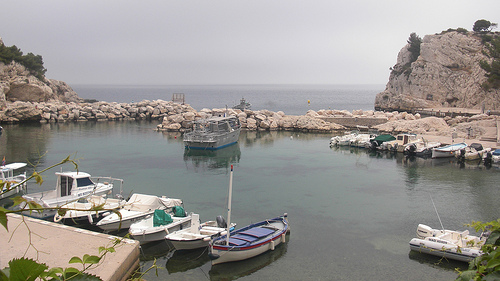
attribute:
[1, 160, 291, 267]
boats — lined, reflected, seven, several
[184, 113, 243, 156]
boat — large, alone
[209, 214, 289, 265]
boat — blue, small, white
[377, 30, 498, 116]
cliff — large, rocky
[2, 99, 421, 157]
rocks — reef, lined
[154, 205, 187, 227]
tarp — green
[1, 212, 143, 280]
platform — wooden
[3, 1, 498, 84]
sky — gray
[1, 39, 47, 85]
bush — green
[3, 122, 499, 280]
water — calm, boat, distant, beyond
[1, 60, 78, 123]
wall — rock